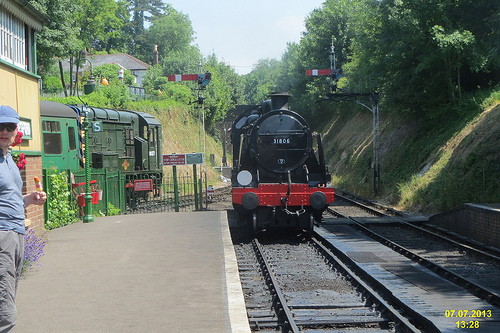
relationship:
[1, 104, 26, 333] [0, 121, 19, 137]
woman wearing sunglasses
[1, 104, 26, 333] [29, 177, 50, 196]
woman holding popsicle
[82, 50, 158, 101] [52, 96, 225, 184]
house on hill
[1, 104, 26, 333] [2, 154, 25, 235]
woman wearing shirt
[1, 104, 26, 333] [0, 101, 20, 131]
woman wearing hat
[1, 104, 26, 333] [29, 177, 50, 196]
woman eating popsicle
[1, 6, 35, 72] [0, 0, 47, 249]
windows of train station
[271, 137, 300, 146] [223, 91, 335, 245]
number on train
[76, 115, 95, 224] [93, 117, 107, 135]
pole has s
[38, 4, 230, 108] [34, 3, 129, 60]
trees have leaves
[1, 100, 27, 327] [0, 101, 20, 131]
person in hat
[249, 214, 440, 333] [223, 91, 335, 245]
track under train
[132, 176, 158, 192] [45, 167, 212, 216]
sign on fence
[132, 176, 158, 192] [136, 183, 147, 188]
sign has words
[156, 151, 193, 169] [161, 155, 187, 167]
sign has words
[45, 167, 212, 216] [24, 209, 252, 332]
fence on platform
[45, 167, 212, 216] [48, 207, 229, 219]
fence on edge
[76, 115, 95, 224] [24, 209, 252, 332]
pole on platform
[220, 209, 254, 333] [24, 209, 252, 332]
line on platform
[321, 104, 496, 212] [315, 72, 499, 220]
grass on hill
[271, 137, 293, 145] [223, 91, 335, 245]
number on train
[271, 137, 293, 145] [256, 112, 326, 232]
number on front